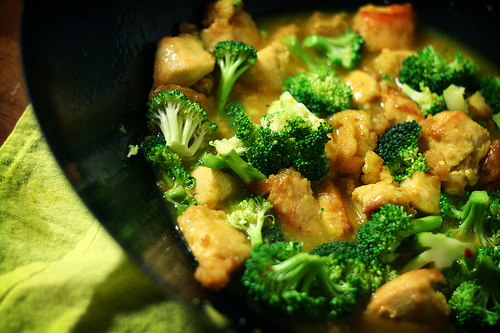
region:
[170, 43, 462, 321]
Chicken and Broccoli in a pan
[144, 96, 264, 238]
Chicken and Broccoli in a pan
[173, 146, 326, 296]
Chicken and Broccoli in a pan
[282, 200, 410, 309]
Chicken and Broccoli in a pan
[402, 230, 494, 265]
Chicken and Broccoli in a pan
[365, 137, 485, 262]
Chicken and Broccoli in a pan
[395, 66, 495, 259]
Chicken and Broccoli in a pan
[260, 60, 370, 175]
Chicken and Broccoli in a pan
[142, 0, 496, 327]
chicken and broccoli cooked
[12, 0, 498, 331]
cooked chicken and broccoli in a large black Wok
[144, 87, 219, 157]
piece of broccoli being cooked in a large Wok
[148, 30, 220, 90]
piece of chicken being cooked in a black Wok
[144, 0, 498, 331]
chicken and broccoli cooking in a brown sauce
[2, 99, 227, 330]
bright green placemat underneath black bowl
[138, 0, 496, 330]
a mix of food being cooked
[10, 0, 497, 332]
a meal being served in a black bowl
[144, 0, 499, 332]
cooked broccoli and chicken meal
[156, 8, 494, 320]
brown sauce cooked with chicken and broccoli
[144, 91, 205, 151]
A green fresh vegitable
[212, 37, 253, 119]
A green fresh vegitable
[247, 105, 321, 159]
A green fresh vegitable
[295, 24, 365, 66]
A green fresh vegitable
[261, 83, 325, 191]
A green fresh vegitable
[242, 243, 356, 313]
A green fresh vegitable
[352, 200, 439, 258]
A green fresh vegitable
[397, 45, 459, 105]
A green fresh vegitable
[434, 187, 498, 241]
A green fresh vegitable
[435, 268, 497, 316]
A green fresh vegitable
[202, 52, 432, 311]
the food is spicy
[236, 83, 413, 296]
the food is delivcious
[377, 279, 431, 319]
the meat is brown oimn color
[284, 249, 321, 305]
vegetable is green in color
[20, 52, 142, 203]
plate is black in color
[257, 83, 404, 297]
food is green and brown in color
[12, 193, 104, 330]
towel is yellow green in color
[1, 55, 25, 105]
table is brown in color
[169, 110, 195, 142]
the baccon has white parts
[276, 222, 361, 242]
the soup is brown in color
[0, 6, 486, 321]
food in a black bowl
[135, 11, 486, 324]
broccoli and chicken dish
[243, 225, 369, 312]
broccoli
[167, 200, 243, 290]
chicken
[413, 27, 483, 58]
sauce bathing the chicken and broccoli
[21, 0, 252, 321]
black bowl holding the food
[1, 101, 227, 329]
towel underneath the bowl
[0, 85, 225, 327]
green towel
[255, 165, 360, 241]
chicken in sauce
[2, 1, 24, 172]
wooden table underneath the fabric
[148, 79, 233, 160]
a cut of broccoli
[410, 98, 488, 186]
the meat is brown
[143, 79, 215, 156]
broccoli next to broccoli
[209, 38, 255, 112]
broccoli next to broccoli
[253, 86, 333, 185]
broccoli next to broccoli